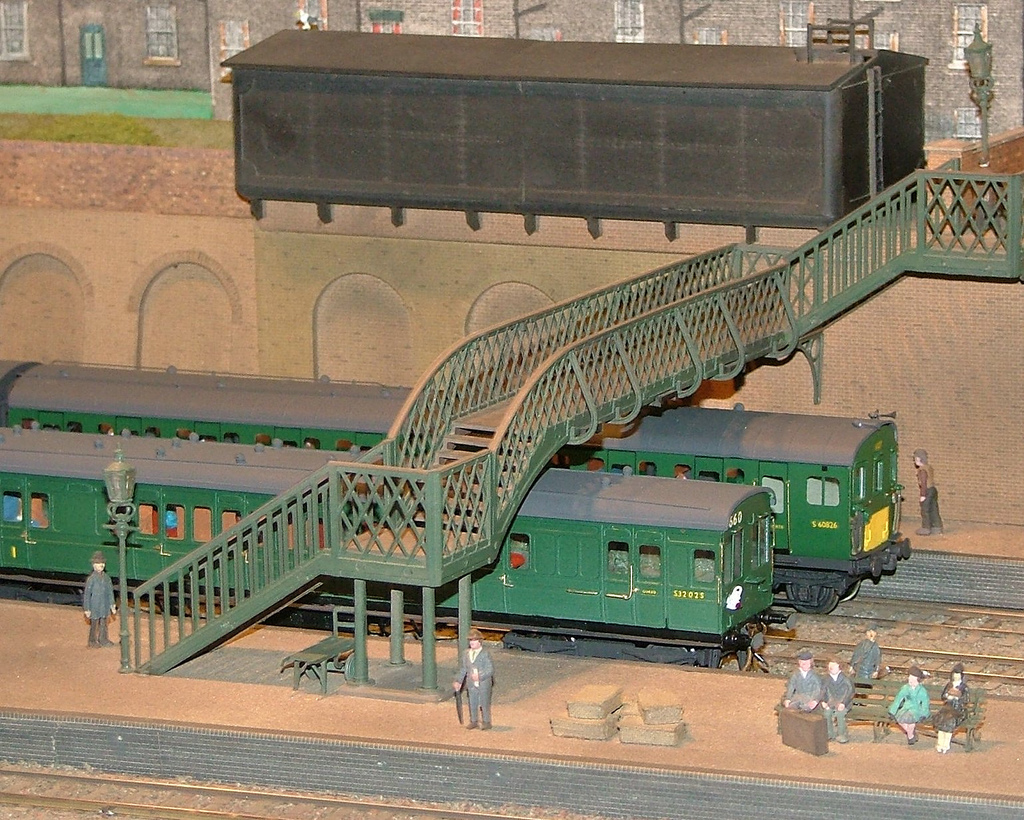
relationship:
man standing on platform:
[85, 547, 120, 649] [44, 655, 133, 700]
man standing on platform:
[443, 620, 510, 735] [500, 660, 551, 736]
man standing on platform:
[781, 655, 826, 716] [718, 717, 763, 769]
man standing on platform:
[847, 614, 890, 682] [828, 737, 886, 780]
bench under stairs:
[278, 623, 370, 694] [124, 442, 480, 664]